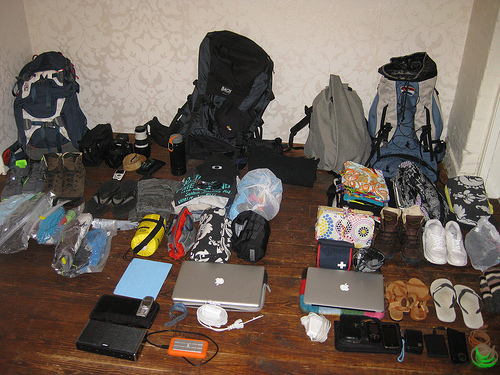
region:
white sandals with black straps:
[429, 271, 482, 328]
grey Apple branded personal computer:
[167, 257, 272, 329]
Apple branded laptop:
[172, 246, 272, 323]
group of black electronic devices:
[339, 316, 470, 371]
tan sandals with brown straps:
[382, 268, 431, 329]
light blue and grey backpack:
[358, 38, 453, 195]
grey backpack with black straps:
[278, 69, 375, 189]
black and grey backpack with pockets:
[156, 14, 286, 179]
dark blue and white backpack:
[8, 50, 103, 172]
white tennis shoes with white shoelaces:
[419, 219, 472, 275]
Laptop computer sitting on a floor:
[171, 255, 267, 307]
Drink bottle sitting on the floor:
[162, 127, 188, 178]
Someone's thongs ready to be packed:
[427, 270, 483, 330]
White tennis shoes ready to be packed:
[416, 213, 468, 269]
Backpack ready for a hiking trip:
[286, 66, 371, 167]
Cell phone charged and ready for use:
[131, 291, 156, 317]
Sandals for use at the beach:
[382, 267, 430, 322]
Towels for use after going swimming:
[445, 167, 491, 222]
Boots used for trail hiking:
[40, 145, 90, 205]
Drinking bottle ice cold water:
[164, 127, 194, 181]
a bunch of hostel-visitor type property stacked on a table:
[0, 24, 498, 374]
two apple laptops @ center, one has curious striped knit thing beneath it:
[163, 250, 393, 325]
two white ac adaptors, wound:
[189, 298, 334, 355]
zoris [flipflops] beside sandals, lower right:
[381, 271, 487, 336]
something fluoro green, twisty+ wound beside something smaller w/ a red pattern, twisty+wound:
[465, 321, 498, 373]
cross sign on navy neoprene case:
[332, 256, 347, 272]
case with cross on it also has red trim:
[313, 234, 357, 279]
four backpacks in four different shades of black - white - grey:
[1, 16, 466, 189]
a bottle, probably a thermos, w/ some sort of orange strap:
[160, 125, 191, 180]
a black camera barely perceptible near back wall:
[94, 118, 145, 174]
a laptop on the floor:
[168, 258, 275, 312]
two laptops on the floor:
[156, 266, 391, 321]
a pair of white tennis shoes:
[422, 220, 469, 262]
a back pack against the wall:
[4, 42, 89, 172]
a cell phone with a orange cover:
[164, 333, 220, 361]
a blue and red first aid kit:
[291, 230, 361, 272]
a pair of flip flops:
[422, 276, 486, 326]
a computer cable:
[191, 299, 270, 332]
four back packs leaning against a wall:
[23, 32, 459, 187]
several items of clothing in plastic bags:
[6, 187, 103, 270]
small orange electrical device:
[138, 315, 222, 372]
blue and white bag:
[6, 40, 99, 170]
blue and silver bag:
[162, 20, 279, 176]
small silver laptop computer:
[286, 251, 401, 327]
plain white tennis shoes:
[408, 204, 470, 275]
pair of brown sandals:
[371, 262, 439, 332]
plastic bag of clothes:
[221, 156, 291, 234]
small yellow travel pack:
[116, 197, 176, 271]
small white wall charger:
[284, 300, 346, 352]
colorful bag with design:
[301, 192, 384, 264]